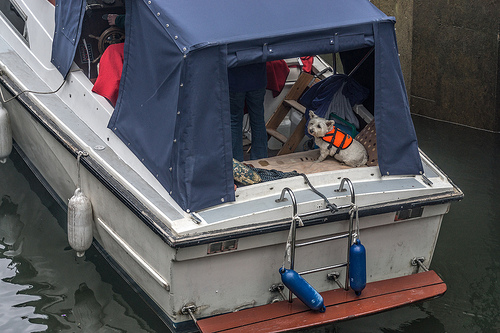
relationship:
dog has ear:
[307, 110, 368, 168] [323, 117, 335, 131]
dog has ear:
[307, 110, 368, 168] [307, 111, 317, 122]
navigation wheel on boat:
[96, 18, 136, 63] [0, 0, 455, 332]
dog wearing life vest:
[307, 110, 368, 168] [318, 124, 353, 150]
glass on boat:
[0, 0, 28, 47] [0, 0, 455, 332]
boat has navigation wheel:
[16, 19, 498, 320] [88, 25, 125, 63]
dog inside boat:
[303, 110, 370, 167] [0, 0, 455, 332]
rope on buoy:
[346, 200, 363, 232] [346, 200, 366, 299]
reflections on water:
[0, 125, 500, 328] [8, 100, 498, 322]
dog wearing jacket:
[307, 110, 368, 168] [321, 125, 353, 157]